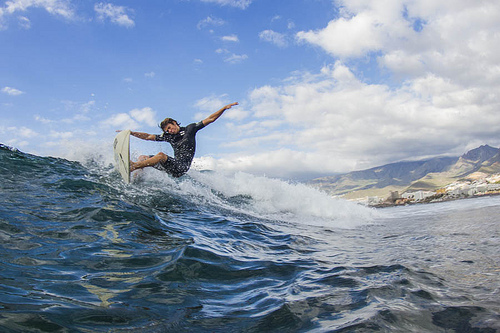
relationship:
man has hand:
[116, 102, 240, 178] [223, 99, 239, 109]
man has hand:
[116, 102, 240, 178] [114, 128, 132, 133]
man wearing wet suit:
[116, 102, 240, 178] [149, 118, 205, 178]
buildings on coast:
[389, 180, 499, 202] [339, 191, 499, 210]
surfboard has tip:
[101, 121, 139, 186] [117, 128, 136, 135]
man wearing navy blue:
[116, 102, 240, 178] [115, 120, 252, 182]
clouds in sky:
[308, 12, 421, 68] [1, 1, 499, 173]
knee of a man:
[152, 149, 169, 179] [85, 80, 240, 215]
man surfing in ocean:
[100, 95, 242, 200] [11, 167, 354, 322]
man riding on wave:
[116, 102, 240, 178] [0, 153, 496, 328]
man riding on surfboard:
[116, 102, 240, 178] [112, 127, 132, 180]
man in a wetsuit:
[116, 102, 240, 178] [154, 129, 201, 178]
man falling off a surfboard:
[116, 102, 240, 178] [111, 121, 135, 185]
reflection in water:
[90, 222, 164, 302] [54, 196, 389, 314]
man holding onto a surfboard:
[116, 102, 240, 178] [98, 116, 155, 184]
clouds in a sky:
[294, 9, 472, 132] [9, 6, 346, 140]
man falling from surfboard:
[116, 102, 240, 178] [111, 130, 132, 183]